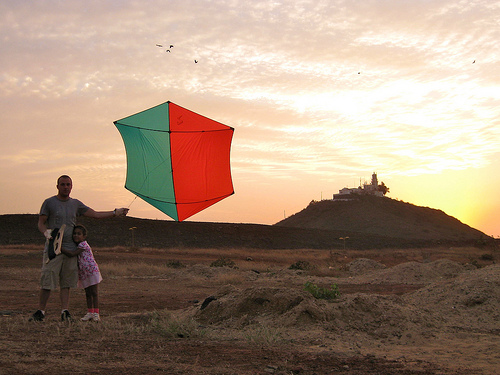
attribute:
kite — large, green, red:
[100, 95, 237, 232]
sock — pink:
[92, 305, 100, 315]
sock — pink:
[84, 304, 94, 314]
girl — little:
[60, 221, 103, 324]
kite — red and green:
[112, 99, 239, 225]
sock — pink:
[91, 306, 99, 313]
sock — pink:
[85, 306, 92, 313]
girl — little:
[68, 220, 115, 310]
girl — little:
[64, 234, 101, 326]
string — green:
[119, 189, 134, 210]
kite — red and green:
[98, 76, 238, 265]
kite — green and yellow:
[104, 107, 322, 262]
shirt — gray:
[35, 196, 90, 248]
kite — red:
[109, 95, 249, 232]